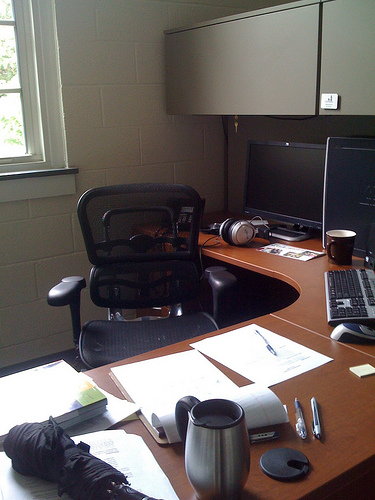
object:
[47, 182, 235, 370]
office chair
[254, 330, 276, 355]
pen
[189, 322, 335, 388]
paper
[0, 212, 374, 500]
desk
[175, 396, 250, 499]
mug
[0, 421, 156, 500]
umbrella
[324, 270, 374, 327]
keyboard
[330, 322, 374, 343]
mouse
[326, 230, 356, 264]
mug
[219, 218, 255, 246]
headphones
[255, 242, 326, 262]
brochure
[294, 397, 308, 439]
pens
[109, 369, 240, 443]
clipboard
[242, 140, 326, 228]
computer monitor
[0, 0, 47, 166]
window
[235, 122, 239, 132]
key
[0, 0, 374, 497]
computer office